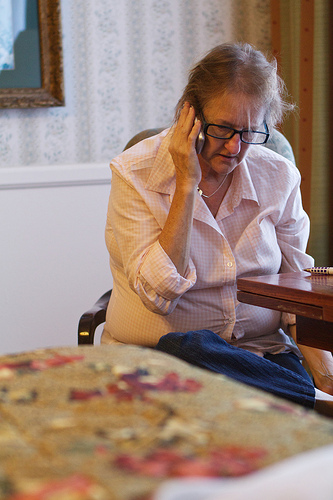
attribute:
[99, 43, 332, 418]
woman — old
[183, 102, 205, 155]
phone — silver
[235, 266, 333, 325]
table — wood, brown, wooden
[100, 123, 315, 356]
shirt — gingham, pink, checkered, white, bunched, collared, buttoned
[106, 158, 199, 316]
sleeve — rolled up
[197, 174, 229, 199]
jewelry — silver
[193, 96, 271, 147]
glasses — black, black framed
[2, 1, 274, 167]
wallpaper — white, blue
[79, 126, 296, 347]
chair — brown, wooden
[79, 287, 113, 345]
arm — curved, brown, wooden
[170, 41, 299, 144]
hair — messy, brown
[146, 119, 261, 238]
collar — open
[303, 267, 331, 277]
fountain pen — white, blue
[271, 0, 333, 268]
curtain — striped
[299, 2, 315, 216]
stripe — orange, dotted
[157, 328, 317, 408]
pants — blue